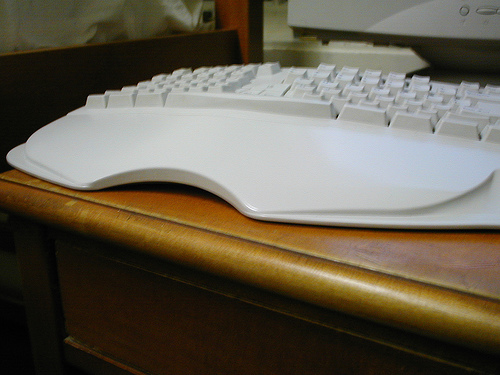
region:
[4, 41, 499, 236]
white keyboard on a desk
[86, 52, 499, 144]
keys on the keyboard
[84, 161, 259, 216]
curve on the bottom of the keyboard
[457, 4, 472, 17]
button on the monitor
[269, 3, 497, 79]
white monitor on the desk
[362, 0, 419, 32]
line on the monitor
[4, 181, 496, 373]
edge of the desk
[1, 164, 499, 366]
light brown wooden desk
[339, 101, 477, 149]
row of three keys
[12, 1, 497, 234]
keyboard by a computer monitor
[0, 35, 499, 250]
white keyboard on the desk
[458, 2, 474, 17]
small circular button on the monitor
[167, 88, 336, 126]
long white spacebar on the keyboard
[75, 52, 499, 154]
several keys on the keyboard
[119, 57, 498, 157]
white computer keyboard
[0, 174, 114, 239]
edge of brown desk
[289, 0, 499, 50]
bottom of the computer monitor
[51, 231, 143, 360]
edge of a drawer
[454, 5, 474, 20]
small round button in the monitor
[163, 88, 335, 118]
space bar on the keyboard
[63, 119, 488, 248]
wrist rest on the keyboard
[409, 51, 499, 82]
base of the computer monitor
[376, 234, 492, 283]
stained top of desk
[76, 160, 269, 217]
indent on bottom of keyboard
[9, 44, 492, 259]
large white keyboard on the desk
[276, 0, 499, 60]
white monitor sitting on the desk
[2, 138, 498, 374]
desk is made of wood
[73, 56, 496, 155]
numerous keys on the board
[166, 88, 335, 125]
long white spacebar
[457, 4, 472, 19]
small button on the monitor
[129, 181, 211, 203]
shadow from the keyboard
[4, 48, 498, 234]
this is a keyboard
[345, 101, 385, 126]
this is a key on the key board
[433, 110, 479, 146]
this is a key on the key board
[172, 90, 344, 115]
this is a key on the key board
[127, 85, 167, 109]
this is a key on the key board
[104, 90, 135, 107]
this is a key on the key board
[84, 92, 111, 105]
this is a key on the key board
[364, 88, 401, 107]
this is a key on the key board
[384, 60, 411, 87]
this is a key on the key board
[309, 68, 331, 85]
this is a key on the key board